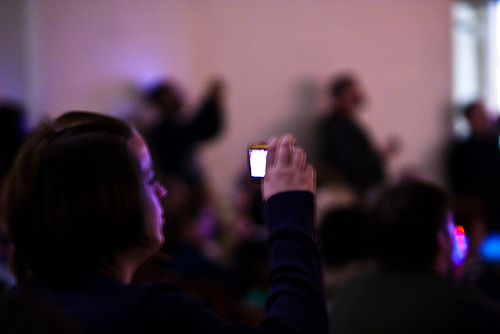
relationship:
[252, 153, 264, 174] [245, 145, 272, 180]
light from camera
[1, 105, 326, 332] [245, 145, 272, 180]
lady holding camera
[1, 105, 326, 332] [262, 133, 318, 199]
lady has hand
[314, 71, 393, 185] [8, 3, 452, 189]
person leaning on wall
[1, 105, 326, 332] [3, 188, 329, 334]
lady wearing sweater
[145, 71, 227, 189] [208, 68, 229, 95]
another person using cell phone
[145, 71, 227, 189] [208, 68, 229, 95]
another person holding cell phone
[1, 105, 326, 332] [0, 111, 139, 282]
lady has hair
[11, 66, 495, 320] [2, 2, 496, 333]
people in picture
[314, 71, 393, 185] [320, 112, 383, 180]
person wearing jacket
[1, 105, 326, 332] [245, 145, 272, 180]
lady holding cell phone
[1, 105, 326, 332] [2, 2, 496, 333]
lady in picture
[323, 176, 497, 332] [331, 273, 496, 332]
man has shirt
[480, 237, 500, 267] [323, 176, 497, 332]
blue light in front of man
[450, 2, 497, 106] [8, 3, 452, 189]
window light near wall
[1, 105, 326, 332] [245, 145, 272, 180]
lady using camera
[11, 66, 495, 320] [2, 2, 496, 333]
people are in picture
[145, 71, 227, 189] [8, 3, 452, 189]
another person leaning on wall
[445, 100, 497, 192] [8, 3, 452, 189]
blurry person near wall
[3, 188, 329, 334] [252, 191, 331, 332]
sweater has sleeve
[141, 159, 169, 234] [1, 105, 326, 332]
glow on lady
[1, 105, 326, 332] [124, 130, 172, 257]
lady has face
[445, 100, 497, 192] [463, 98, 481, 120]
blurry person has brown hair